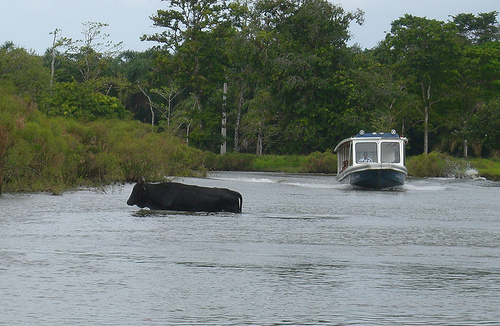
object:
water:
[0, 169, 499, 326]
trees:
[2, 21, 131, 123]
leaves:
[34, 80, 131, 123]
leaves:
[362, 9, 499, 151]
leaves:
[136, 0, 212, 45]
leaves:
[201, 107, 223, 143]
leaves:
[229, 86, 301, 147]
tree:
[0, 92, 86, 199]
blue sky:
[0, 0, 500, 49]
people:
[341, 159, 349, 172]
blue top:
[355, 129, 398, 138]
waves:
[210, 170, 355, 189]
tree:
[84, 110, 179, 194]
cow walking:
[126, 176, 243, 214]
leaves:
[2, 18, 131, 76]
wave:
[403, 155, 500, 192]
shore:
[211, 150, 500, 179]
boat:
[331, 129, 408, 189]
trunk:
[218, 70, 270, 158]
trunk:
[417, 70, 434, 154]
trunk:
[462, 134, 488, 159]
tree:
[363, 9, 499, 158]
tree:
[245, 0, 422, 159]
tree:
[140, 0, 368, 146]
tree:
[61, 20, 135, 115]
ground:
[328, 94, 375, 114]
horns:
[139, 175, 146, 184]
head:
[126, 176, 159, 208]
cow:
[127, 176, 243, 214]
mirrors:
[338, 142, 354, 170]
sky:
[2, 0, 497, 62]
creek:
[1, 169, 500, 325]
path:
[191, 172, 467, 195]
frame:
[350, 129, 403, 167]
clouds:
[0, 0, 171, 56]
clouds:
[340, 0, 499, 53]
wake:
[204, 157, 488, 200]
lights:
[359, 128, 396, 136]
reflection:
[128, 209, 244, 220]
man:
[358, 151, 373, 163]